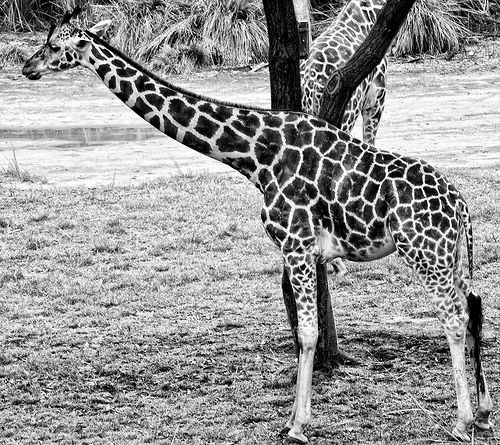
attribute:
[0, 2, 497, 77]
large shrubs — grass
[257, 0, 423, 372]
tree — dark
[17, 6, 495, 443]
giraffe — large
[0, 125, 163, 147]
area — wet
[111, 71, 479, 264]
fur — combed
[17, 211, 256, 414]
grass — short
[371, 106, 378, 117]
patches — black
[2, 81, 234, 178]
pond — small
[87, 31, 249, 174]
neck — long 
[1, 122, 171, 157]
water — murky 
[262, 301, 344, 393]
leg — long 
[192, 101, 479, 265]
skin — brown, white, polygon shape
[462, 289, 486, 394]
hair — dark 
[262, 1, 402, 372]
tree — dark 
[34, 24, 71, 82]
eye — dark 